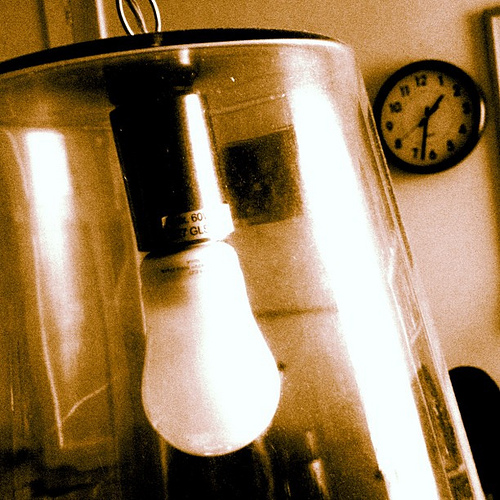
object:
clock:
[370, 59, 487, 175]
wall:
[3, 1, 496, 383]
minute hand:
[421, 106, 429, 160]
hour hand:
[427, 93, 444, 117]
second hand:
[395, 117, 426, 146]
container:
[2, 34, 487, 500]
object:
[447, 365, 500, 500]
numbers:
[384, 73, 473, 162]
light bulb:
[141, 243, 281, 455]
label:
[157, 259, 203, 280]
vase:
[285, 430, 331, 500]